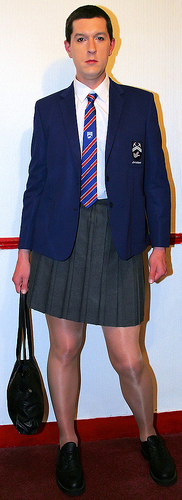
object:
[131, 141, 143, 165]
emblem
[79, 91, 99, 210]
neck tie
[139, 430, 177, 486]
shoe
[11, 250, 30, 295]
hand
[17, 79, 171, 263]
blazer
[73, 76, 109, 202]
shirt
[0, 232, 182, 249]
strip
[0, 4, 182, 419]
wall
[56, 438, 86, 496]
feet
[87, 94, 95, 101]
stripe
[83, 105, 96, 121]
stripe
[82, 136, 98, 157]
stripe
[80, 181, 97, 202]
stripe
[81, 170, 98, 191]
stripe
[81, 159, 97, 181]
stripe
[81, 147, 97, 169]
stripe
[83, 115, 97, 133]
stripe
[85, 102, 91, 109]
stripe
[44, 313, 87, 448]
pantyhose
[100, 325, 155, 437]
pantyhose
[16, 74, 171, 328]
uniform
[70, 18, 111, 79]
makeup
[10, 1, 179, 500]
man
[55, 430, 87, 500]
shoe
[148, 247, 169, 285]
hand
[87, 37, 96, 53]
nose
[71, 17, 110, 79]
face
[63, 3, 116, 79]
head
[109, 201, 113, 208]
button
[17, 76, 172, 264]
clothing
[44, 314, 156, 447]
clothing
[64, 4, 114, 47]
hair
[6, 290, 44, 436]
bag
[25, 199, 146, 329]
skirt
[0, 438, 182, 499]
carpet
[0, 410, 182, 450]
floor